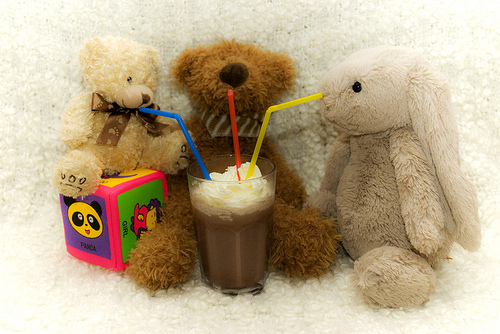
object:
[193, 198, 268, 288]
chocolate soda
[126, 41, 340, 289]
bear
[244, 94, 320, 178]
straw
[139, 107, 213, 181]
straw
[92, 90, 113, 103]
neck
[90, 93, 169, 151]
ribbon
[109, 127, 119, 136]
paw print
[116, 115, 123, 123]
paw print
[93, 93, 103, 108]
paw print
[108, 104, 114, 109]
paw print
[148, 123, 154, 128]
paw print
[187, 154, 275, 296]
glass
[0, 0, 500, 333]
blanket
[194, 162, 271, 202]
whipped cream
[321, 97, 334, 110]
nose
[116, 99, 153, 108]
chin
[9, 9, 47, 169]
poodle fur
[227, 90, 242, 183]
red straw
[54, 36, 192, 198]
baby bear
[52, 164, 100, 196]
foot pad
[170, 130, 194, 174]
foot pad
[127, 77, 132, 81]
eye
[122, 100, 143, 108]
mouth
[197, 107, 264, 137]
neckerchief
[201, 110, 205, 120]
stripe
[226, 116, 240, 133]
stripe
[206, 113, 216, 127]
stripe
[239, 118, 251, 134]
stripe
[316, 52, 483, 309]
bunster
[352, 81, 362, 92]
eye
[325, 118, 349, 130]
moved down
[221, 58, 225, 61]
eye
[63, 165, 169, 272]
block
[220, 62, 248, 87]
nose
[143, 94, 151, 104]
nose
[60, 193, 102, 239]
outline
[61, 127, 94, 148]
forepaw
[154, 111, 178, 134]
[hidden] forepaw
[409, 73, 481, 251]
ear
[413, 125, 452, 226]
hidden 2nd ear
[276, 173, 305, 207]
forepaw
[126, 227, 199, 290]
hind paw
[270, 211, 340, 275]
hind paw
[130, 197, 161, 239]
picture of girl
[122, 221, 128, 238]
'girl' [the word]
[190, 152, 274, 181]
room behind cream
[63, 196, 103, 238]
'panda'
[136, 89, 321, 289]
soda+cream together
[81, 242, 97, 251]
'panda' [the word]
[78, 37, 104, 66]
ear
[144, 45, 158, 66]
ear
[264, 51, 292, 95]
ear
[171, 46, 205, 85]
ear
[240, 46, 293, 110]
side of head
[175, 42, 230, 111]
side of head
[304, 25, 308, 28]
little bare spot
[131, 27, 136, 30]
little bare spot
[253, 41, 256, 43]
little bare spot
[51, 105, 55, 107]
little bare spot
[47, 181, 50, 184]
little bare spot